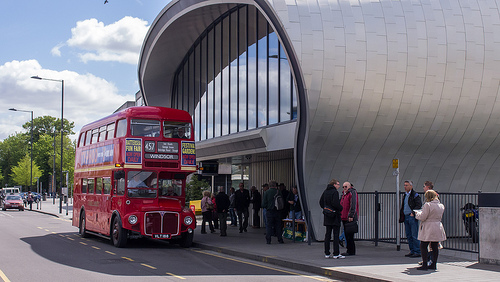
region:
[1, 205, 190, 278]
dash of yellow lines on a street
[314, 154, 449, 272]
men and women standing at a bus stop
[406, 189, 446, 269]
woman standing on a sidewalk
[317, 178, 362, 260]
two people standing on a sidewalk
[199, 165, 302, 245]
group of people near a buildings entrance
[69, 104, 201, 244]
red bus on a street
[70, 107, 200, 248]
double decker bus on a street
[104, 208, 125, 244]
front wheel of a bus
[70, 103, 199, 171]
upper level of a double decker bus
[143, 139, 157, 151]
front number print on a bus reading 457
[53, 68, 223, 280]
this is a double decker bus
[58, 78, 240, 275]
this is a bus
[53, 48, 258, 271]
the bus is tall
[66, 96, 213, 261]
the bus is red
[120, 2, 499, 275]
the building has a curved design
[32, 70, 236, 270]
a red double decker bus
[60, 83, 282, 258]
this is a red double decker bus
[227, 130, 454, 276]
they are waiting at a bus stop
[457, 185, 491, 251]
a parked motorcycle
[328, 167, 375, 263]
he is waring a red and grey jacket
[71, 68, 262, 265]
this is a large bus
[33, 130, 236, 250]
the bus has two stories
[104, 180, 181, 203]
these are some windows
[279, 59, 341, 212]
this is a building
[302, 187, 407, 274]
this is a group of people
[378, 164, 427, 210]
this is a pole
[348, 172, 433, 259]
this is a fence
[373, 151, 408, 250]
the fence is black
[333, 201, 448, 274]
the fence is metal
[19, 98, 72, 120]
this is a large light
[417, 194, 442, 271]
person wearing dark pants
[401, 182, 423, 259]
person wearing dark pants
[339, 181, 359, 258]
person wearing dark pants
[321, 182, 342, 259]
person wearing dark pants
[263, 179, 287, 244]
person wearing dark pants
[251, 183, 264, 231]
person wearing dark pants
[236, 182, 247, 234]
person wearing dark pants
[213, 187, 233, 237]
person wearing dark pants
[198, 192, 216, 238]
person wearing dark pants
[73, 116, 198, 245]
red double decker bus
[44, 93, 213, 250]
a two story bus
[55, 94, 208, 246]
a red bus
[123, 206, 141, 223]
headlight on the bus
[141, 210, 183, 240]
the grill on a bus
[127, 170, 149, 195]
driver of the bus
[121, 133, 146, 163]
advertisment on the bus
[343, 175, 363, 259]
a man wearing sunglasses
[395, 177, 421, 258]
a man with his hands in his pockets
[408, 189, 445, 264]
a woman wearing a jacket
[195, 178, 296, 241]
a group of people on the sidewalk